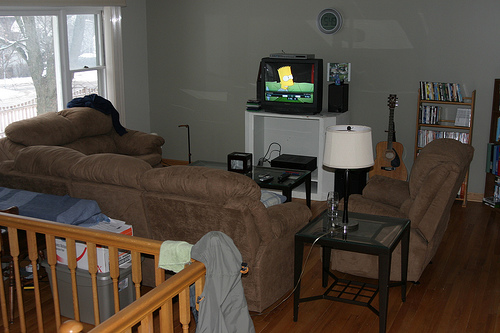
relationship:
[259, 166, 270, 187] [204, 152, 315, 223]
remote on side table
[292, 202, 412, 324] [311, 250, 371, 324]
stool has stand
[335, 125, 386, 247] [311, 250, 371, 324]
lamp has stand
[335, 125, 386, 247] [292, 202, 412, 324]
lamp on side table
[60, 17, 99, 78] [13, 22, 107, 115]
screen on window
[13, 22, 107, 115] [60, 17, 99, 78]
window has screen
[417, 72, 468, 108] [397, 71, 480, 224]
books on top of shelf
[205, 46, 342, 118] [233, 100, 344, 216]
tv on stand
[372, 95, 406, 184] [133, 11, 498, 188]
guitar leaning on wall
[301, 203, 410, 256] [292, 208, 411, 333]
glass on stand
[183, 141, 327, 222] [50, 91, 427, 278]
table between chairs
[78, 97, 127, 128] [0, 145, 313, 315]
clothes on chairs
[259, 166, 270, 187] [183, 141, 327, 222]
remote on top of table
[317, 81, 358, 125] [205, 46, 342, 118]
speaker near tv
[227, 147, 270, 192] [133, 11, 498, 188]
dvd near wall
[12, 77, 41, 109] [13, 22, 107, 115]
snow outside window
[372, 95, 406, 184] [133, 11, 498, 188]
guitar sits on wall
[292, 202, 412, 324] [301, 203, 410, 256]
side table has top of glass